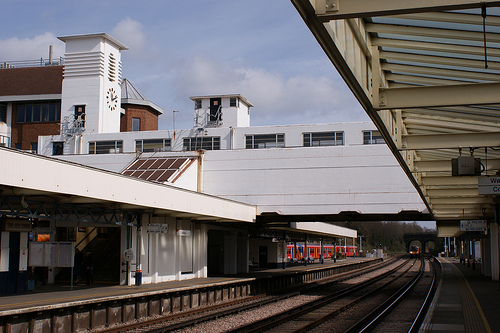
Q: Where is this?
A: Train station.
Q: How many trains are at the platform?
A: Zero.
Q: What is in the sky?
A: Clouds.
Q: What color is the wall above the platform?
A: White.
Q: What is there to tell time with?
A: Clock.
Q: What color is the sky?
A: Blue.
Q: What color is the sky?
A: Blue.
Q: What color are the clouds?
A: White.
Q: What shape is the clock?
A: Circle.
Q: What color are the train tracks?
A: Brown.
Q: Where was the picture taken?
A: A train station.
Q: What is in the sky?
A: Clouds.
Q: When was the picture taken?
A: Daytime.